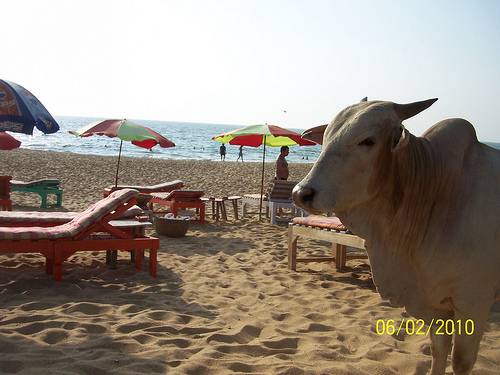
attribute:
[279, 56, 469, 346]
cow — tan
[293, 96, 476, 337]
cow — tan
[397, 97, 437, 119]
horn — grey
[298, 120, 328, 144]
horn — grey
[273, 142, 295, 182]
man — standing 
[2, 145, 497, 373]
sand — light brown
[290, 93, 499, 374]
cow — tan, white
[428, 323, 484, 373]
legs — white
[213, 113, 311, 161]
umbrella — red, yellow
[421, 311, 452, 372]
leg — in front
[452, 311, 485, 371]
leg — in front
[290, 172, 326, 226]
nose — brown